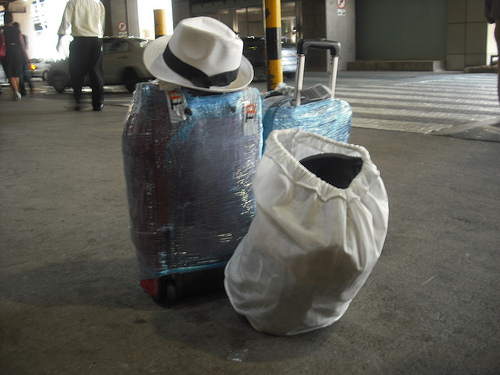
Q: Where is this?
A: This is at the walkway.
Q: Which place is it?
A: It is a walkway.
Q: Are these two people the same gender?
A: No, they are both male and female.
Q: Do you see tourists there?
A: No, there are no tourists.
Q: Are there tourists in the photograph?
A: No, there are no tourists.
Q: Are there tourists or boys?
A: No, there are no tourists or boys.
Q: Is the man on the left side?
A: Yes, the man is on the left of the image.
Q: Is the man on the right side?
A: No, the man is on the left of the image.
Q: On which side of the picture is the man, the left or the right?
A: The man is on the left of the image.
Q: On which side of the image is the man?
A: The man is on the left of the image.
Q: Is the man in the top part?
A: Yes, the man is in the top of the image.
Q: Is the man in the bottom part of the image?
A: No, the man is in the top of the image.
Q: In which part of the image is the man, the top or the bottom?
A: The man is in the top of the image.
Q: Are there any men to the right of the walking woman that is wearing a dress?
A: Yes, there is a man to the right of the woman.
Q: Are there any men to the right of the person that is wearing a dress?
A: Yes, there is a man to the right of the woman.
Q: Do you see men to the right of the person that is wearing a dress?
A: Yes, there is a man to the right of the woman.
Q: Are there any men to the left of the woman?
A: No, the man is to the right of the woman.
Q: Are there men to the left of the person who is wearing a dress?
A: No, the man is to the right of the woman.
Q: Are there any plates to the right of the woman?
A: No, there is a man to the right of the woman.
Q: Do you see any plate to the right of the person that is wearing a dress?
A: No, there is a man to the right of the woman.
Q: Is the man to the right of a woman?
A: Yes, the man is to the right of a woman.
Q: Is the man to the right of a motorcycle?
A: No, the man is to the right of a woman.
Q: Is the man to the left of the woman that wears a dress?
A: No, the man is to the right of the woman.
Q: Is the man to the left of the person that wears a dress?
A: No, the man is to the right of the woman.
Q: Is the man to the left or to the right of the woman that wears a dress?
A: The man is to the right of the woman.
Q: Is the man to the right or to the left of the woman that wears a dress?
A: The man is to the right of the woman.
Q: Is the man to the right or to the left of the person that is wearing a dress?
A: The man is to the right of the woman.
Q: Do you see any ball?
A: No, there are no balls.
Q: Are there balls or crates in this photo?
A: No, there are no balls or crates.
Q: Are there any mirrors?
A: No, there are no mirrors.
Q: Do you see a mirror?
A: No, there are no mirrors.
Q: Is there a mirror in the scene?
A: No, there are no mirrors.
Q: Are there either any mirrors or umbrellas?
A: No, there are no mirrors or umbrellas.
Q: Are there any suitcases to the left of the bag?
A: Yes, there is a suitcase to the left of the bag.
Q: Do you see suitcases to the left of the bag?
A: Yes, there is a suitcase to the left of the bag.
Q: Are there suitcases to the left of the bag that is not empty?
A: Yes, there is a suitcase to the left of the bag.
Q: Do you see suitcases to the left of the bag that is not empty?
A: Yes, there is a suitcase to the left of the bag.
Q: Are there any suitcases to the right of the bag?
A: No, the suitcase is to the left of the bag.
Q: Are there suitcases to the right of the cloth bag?
A: No, the suitcase is to the left of the bag.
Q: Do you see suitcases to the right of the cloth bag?
A: No, the suitcase is to the left of the bag.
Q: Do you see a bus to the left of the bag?
A: No, there is a suitcase to the left of the bag.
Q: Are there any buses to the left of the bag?
A: No, there is a suitcase to the left of the bag.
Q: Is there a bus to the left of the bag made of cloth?
A: No, there is a suitcase to the left of the bag.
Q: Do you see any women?
A: Yes, there is a woman.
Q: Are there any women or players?
A: Yes, there is a woman.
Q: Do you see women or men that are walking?
A: Yes, the woman is walking.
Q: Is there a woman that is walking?
A: Yes, there is a woman that is walking.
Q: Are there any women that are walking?
A: Yes, there is a woman that is walking.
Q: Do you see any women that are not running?
A: Yes, there is a woman that is walking .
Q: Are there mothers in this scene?
A: No, there are no mothers.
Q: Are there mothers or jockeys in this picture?
A: No, there are no mothers or jockeys.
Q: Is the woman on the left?
A: Yes, the woman is on the left of the image.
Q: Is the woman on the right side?
A: No, the woman is on the left of the image.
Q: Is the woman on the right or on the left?
A: The woman is on the left of the image.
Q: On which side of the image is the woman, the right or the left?
A: The woman is on the left of the image.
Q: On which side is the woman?
A: The woman is on the left of the image.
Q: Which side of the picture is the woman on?
A: The woman is on the left of the image.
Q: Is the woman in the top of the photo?
A: Yes, the woman is in the top of the image.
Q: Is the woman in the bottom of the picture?
A: No, the woman is in the top of the image.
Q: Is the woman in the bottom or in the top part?
A: The woman is in the top of the image.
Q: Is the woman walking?
A: Yes, the woman is walking.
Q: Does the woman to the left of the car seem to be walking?
A: Yes, the woman is walking.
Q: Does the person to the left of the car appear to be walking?
A: Yes, the woman is walking.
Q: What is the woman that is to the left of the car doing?
A: The woman is walking.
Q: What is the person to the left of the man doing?
A: The woman is walking.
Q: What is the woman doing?
A: The woman is walking.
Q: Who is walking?
A: The woman is walking.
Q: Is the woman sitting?
A: No, the woman is walking.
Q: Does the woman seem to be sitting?
A: No, the woman is walking.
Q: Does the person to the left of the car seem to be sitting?
A: No, the woman is walking.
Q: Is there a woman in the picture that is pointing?
A: No, there is a woman but she is walking.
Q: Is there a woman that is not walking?
A: No, there is a woman but she is walking.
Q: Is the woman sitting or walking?
A: The woman is walking.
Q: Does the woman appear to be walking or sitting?
A: The woman is walking.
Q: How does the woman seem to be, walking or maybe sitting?
A: The woman is walking.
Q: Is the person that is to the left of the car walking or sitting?
A: The woman is walking.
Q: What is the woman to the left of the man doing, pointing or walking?
A: The woman is walking.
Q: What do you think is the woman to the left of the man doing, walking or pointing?
A: The woman is walking.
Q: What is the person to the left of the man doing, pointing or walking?
A: The woman is walking.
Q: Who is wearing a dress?
A: The woman is wearing a dress.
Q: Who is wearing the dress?
A: The woman is wearing a dress.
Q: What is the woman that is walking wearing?
A: The woman is wearing a dress.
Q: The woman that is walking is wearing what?
A: The woman is wearing a dress.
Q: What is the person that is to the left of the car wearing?
A: The woman is wearing a dress.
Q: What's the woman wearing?
A: The woman is wearing a dress.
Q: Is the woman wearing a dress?
A: Yes, the woman is wearing a dress.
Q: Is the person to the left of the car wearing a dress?
A: Yes, the woman is wearing a dress.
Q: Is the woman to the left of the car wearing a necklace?
A: No, the woman is wearing a dress.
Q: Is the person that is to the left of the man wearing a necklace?
A: No, the woman is wearing a dress.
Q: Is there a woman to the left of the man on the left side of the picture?
A: Yes, there is a woman to the left of the man.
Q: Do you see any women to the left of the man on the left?
A: Yes, there is a woman to the left of the man.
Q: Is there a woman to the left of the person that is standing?
A: Yes, there is a woman to the left of the man.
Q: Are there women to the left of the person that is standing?
A: Yes, there is a woman to the left of the man.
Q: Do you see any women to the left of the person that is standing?
A: Yes, there is a woman to the left of the man.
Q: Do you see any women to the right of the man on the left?
A: No, the woman is to the left of the man.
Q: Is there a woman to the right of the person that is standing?
A: No, the woman is to the left of the man.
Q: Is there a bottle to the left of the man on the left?
A: No, there is a woman to the left of the man.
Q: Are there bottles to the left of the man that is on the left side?
A: No, there is a woman to the left of the man.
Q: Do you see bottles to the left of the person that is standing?
A: No, there is a woman to the left of the man.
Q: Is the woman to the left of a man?
A: Yes, the woman is to the left of a man.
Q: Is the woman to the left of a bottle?
A: No, the woman is to the left of a man.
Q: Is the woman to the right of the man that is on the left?
A: No, the woman is to the left of the man.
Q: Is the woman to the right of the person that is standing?
A: No, the woman is to the left of the man.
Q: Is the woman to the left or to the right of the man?
A: The woman is to the left of the man.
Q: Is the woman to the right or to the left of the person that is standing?
A: The woman is to the left of the man.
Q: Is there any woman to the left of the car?
A: Yes, there is a woman to the left of the car.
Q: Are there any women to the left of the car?
A: Yes, there is a woman to the left of the car.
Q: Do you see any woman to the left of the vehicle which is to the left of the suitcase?
A: Yes, there is a woman to the left of the car.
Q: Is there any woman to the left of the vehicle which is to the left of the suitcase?
A: Yes, there is a woman to the left of the car.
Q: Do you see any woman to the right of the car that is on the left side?
A: No, the woman is to the left of the car.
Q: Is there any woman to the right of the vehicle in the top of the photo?
A: No, the woman is to the left of the car.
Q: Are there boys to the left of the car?
A: No, there is a woman to the left of the car.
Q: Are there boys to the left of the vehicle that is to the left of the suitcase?
A: No, there is a woman to the left of the car.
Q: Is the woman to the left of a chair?
A: No, the woman is to the left of the car.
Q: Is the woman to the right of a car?
A: No, the woman is to the left of a car.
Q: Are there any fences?
A: No, there are no fences.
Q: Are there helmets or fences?
A: No, there are no fences or helmets.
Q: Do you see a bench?
A: No, there are no benches.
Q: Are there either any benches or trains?
A: No, there are no benches or trains.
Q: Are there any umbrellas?
A: No, there are no umbrellas.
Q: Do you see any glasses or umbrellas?
A: No, there are no umbrellas or glasses.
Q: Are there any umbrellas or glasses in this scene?
A: No, there are no umbrellas or glasses.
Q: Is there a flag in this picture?
A: No, there are no flags.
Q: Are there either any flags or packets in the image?
A: No, there are no flags or packets.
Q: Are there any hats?
A: Yes, there is a hat.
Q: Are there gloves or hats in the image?
A: Yes, there is a hat.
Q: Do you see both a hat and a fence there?
A: No, there is a hat but no fences.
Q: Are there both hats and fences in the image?
A: No, there is a hat but no fences.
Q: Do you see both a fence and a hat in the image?
A: No, there is a hat but no fences.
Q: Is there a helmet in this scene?
A: No, there are no helmets.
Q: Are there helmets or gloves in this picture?
A: No, there are no helmets or gloves.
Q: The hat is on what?
A: The hat is on the suitcase.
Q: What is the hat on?
A: The hat is on the suitcase.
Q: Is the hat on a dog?
A: No, the hat is on the suitcase.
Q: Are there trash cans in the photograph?
A: No, there are no trash cans.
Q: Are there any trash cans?
A: No, there are no trash cans.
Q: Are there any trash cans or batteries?
A: No, there are no trash cans or batteries.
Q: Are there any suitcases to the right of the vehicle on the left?
A: Yes, there is a suitcase to the right of the car.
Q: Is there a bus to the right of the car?
A: No, there is a suitcase to the right of the car.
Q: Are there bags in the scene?
A: Yes, there is a bag.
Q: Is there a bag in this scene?
A: Yes, there is a bag.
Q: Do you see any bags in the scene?
A: Yes, there is a bag.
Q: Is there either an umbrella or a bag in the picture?
A: Yes, there is a bag.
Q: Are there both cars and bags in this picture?
A: Yes, there are both a bag and a car.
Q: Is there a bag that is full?
A: Yes, there is a full bag.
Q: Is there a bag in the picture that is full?
A: Yes, there is a bag that is full.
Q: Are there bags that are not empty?
A: Yes, there is an full bag.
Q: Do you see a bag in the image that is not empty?
A: Yes, there is an full bag.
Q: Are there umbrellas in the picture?
A: No, there are no umbrellas.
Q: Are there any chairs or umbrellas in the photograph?
A: No, there are no umbrellas or chairs.